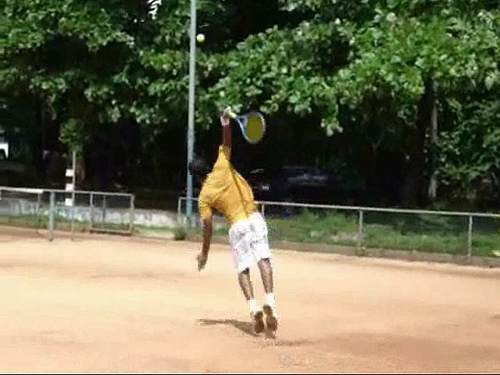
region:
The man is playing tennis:
[155, 98, 292, 330]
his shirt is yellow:
[195, 163, 260, 218]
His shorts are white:
[233, 213, 273, 275]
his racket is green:
[240, 117, 265, 134]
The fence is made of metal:
[260, 197, 493, 265]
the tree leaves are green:
[21, 10, 473, 161]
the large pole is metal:
[180, 2, 196, 223]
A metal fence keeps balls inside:
[2, 175, 151, 250]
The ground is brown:
[55, 262, 201, 374]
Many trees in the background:
[26, 60, 458, 207]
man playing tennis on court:
[143, 78, 318, 330]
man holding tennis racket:
[134, 64, 305, 344]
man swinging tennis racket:
[130, 73, 289, 350]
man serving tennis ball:
[115, 10, 303, 356]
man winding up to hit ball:
[147, 103, 284, 355]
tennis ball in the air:
[181, 22, 208, 55]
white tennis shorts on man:
[207, 200, 282, 280]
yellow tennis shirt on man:
[183, 143, 260, 241]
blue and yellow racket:
[230, 103, 270, 149]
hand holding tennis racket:
[213, 101, 277, 150]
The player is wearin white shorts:
[216, 216, 271, 267]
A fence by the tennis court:
[10, 176, 499, 268]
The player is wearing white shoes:
[246, 297, 278, 329]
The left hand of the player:
[195, 250, 210, 267]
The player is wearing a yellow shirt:
[180, 153, 263, 223]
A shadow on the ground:
[203, 309, 260, 334]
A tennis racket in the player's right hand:
[221, 104, 267, 140]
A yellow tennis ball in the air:
[190, 26, 205, 42]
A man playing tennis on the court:
[188, 108, 292, 333]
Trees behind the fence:
[0, 2, 499, 209]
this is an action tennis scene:
[48, 7, 330, 317]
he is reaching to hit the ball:
[145, 19, 317, 248]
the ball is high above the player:
[160, 14, 292, 160]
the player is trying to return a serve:
[115, 18, 312, 301]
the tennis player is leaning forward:
[113, 127, 335, 332]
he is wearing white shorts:
[213, 219, 299, 341]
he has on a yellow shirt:
[163, 146, 273, 224]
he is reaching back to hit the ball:
[211, 98, 282, 168]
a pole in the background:
[159, 11, 211, 157]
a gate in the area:
[269, 190, 489, 271]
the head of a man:
[186, 149, 216, 185]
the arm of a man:
[198, 197, 215, 258]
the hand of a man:
[191, 250, 211, 273]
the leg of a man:
[226, 223, 261, 305]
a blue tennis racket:
[220, 107, 273, 148]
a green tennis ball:
[215, 87, 232, 99]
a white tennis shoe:
[258, 285, 286, 342]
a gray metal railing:
[0, 180, 498, 268]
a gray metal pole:
[178, 0, 198, 225]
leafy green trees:
[0, 0, 499, 212]